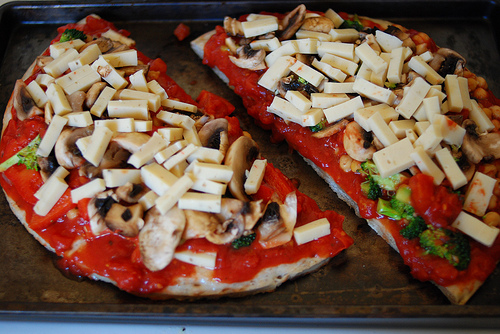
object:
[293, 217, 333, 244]
cheese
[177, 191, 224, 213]
cheese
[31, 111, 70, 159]
cheese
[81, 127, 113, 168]
cheese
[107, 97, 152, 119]
cheese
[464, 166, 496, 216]
cheese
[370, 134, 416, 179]
cheese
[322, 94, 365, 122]
cheese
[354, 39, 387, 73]
cheese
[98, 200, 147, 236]
mushroom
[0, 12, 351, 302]
pizza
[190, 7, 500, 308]
pizza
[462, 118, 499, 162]
mushroom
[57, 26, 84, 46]
broccoli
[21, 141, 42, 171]
broccoli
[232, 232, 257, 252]
broccoli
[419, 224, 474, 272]
broccoli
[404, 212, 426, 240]
broccoli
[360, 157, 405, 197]
broccoli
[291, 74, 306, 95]
broccoli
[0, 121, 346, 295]
sauce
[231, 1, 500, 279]
sauce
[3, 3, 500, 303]
pan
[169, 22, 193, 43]
tomato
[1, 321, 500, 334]
surface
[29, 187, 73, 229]
tomato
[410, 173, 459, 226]
tomato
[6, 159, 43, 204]
tomato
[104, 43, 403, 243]
space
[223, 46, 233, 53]
broccoli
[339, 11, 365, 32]
broccoli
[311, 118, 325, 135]
broccoli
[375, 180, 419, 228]
broccoli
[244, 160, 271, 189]
cheese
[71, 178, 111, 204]
cheese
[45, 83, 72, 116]
cheese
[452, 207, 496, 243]
cheese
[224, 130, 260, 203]
mushroom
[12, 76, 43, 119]
mushroom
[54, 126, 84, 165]
mushroom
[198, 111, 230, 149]
mushroom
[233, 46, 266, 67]
mushroom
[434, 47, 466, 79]
mushroom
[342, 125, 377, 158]
mushroom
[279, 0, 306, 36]
mushroom